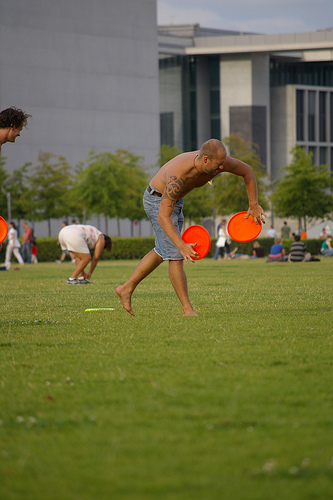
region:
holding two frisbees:
[159, 213, 267, 286]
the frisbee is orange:
[226, 202, 262, 250]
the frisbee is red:
[181, 221, 210, 270]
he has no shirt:
[145, 142, 227, 219]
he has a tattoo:
[161, 163, 185, 208]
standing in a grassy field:
[109, 146, 282, 339]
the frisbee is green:
[56, 288, 133, 330]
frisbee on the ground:
[72, 288, 120, 331]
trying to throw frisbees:
[158, 184, 268, 277]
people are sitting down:
[233, 226, 318, 265]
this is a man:
[120, 124, 265, 333]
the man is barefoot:
[99, 273, 227, 339]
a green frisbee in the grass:
[74, 292, 113, 333]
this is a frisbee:
[213, 199, 281, 267]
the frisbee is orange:
[213, 198, 286, 255]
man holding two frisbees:
[142, 177, 272, 285]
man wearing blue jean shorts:
[135, 176, 201, 266]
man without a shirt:
[128, 128, 260, 223]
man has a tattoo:
[155, 166, 191, 214]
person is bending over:
[46, 206, 125, 300]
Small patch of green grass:
[8, 455, 43, 492]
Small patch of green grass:
[39, 457, 61, 482]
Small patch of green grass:
[74, 455, 109, 485]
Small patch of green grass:
[106, 458, 133, 490]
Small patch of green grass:
[134, 437, 163, 464]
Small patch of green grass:
[161, 460, 183, 487]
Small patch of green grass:
[183, 425, 212, 460]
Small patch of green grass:
[219, 460, 258, 484]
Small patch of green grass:
[245, 410, 280, 434]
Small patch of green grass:
[126, 330, 179, 359]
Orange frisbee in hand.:
[223, 207, 261, 249]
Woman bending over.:
[52, 219, 114, 290]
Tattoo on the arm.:
[157, 169, 187, 214]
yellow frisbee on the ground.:
[82, 305, 119, 314]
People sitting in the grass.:
[266, 230, 318, 265]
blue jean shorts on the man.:
[137, 183, 197, 263]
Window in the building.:
[293, 87, 309, 143]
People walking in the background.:
[4, 218, 41, 270]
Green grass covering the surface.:
[0, 259, 330, 497]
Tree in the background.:
[269, 142, 332, 232]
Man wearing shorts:
[140, 185, 188, 264]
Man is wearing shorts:
[138, 184, 188, 263]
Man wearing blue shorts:
[138, 185, 193, 265]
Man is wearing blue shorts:
[138, 185, 190, 264]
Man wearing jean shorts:
[140, 186, 191, 263]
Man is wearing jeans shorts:
[141, 181, 182, 257]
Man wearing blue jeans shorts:
[138, 184, 190, 262]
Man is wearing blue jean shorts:
[140, 181, 190, 264]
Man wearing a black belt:
[148, 182, 181, 201]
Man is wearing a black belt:
[146, 182, 170, 200]